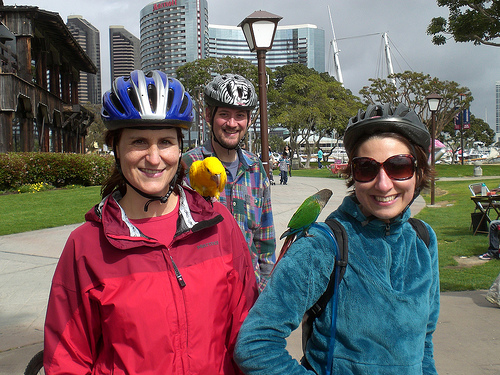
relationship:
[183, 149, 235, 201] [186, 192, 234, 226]
bird sitting on shoulder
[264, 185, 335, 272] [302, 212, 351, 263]
bird sitting on shoulder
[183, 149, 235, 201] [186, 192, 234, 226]
bird sit on shoulder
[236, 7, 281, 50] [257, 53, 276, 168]
lamp on top of post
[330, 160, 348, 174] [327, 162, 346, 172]
table for picnic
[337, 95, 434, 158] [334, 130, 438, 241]
helmet on head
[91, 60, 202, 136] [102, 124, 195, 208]
helmet on head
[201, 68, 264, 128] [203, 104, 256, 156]
helmet on head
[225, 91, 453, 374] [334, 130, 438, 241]
woman has head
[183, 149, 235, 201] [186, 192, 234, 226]
bird on shoulder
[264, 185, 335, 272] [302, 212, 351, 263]
bird on shoulder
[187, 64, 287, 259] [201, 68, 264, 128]
man has helmet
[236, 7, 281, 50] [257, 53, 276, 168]
light on top of pole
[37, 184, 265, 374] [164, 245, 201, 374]
jacket has zipper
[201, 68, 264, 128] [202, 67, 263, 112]
helme with black stripes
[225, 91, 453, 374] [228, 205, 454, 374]
woman wearing jacket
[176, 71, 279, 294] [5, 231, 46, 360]
man standing on road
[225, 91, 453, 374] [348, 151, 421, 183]
woman wearing sunglasses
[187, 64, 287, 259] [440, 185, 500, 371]
man standing in park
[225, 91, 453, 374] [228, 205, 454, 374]
woman wearing blue sweater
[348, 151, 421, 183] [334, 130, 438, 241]
sunglasse are on face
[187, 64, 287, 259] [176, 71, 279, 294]
man behind man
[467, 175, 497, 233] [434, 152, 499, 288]
chair on grass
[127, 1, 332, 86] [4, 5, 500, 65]
building in background